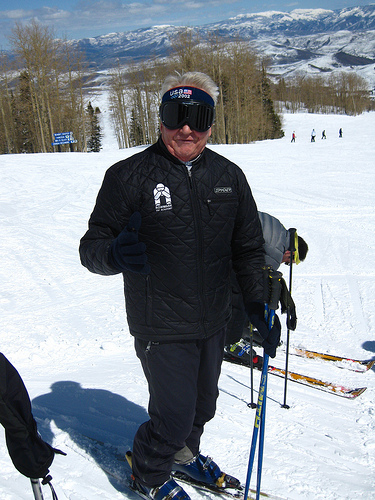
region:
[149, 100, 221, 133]
black goggles over eyes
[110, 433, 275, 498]
pair of ski's on feet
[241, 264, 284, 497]
pair of blue ski poles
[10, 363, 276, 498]
black shadow of skier on ground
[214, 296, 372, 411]
pair of yellow skis on snow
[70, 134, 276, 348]
black quilted ski coat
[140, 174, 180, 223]
white design on front of jacket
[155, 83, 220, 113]
black and red headband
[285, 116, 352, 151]
four people walking across snow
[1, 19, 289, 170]
tall trees in front of snow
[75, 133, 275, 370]
man wearing black jacket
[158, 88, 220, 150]
man wearing black goggles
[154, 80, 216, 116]
man wearing blue headband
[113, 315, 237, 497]
man wearing back pants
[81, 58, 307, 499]
man standing on skis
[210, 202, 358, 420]
man on yellow skis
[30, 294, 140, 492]
ski tracks in snow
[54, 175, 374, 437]
a ground covered in snow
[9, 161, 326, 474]
a ground covered in white snow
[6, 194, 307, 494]
snow covering the ground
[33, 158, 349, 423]
white snow covering the ground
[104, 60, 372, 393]
a man that is skiing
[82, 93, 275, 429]
a man on skies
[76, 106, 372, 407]
a man skiing on the snow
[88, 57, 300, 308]
a man wearing a jacket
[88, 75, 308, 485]
a man wearing a black jacket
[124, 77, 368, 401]
a man wearing a gloves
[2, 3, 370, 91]
a mountain on the background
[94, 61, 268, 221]
man has gray hair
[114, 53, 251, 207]
man wears a headband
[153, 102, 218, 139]
a pair of sunglasses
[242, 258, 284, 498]
a pair of blue poles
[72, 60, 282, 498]
man holds poles on left hand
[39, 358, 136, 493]
a shadow cast on snow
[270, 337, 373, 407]
skis are color yellow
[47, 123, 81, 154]
a blue sign near the trees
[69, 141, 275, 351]
a black coat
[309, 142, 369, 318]
ground with snow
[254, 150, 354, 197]
ski tracks on snow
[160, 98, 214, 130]
ski goggles for eye protection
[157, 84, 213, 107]
usa headband fro 2005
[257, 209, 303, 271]
person bending over at the knee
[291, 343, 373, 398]
front of the pair of skis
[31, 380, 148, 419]
shadow of a human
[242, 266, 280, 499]
ski sticks for balance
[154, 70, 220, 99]
head of white hair, indication of aging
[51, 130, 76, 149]
blue sign with white lettering